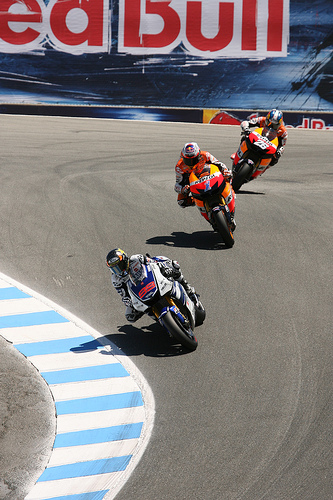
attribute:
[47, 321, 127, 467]
strips — blue, white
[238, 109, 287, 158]
person — right-leaning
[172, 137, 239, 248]
person — left-leaning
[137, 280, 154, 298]
99 — red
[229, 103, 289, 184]
motorcycle — racing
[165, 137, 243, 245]
motorcycle — racing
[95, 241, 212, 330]
motorcycle — racing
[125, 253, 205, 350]
bike — leaning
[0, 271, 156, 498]
strips — white, blue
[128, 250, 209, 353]
motorcycle — blue, white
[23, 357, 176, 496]
strips — white, blue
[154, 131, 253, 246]
bike — blue, white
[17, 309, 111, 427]
stripes — white, blue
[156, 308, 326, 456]
track — paved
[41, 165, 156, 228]
trask — paved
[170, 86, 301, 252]
bikes — matching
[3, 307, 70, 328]
strips — blue, white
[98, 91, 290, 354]
people — racing